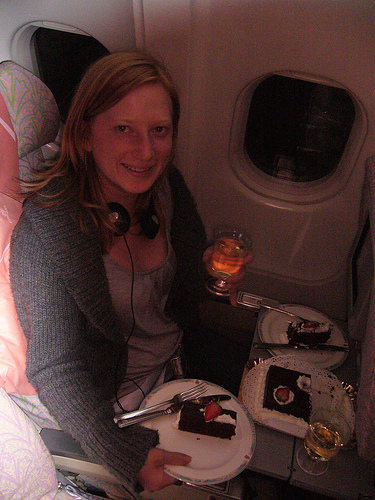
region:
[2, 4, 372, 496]
woman in what appears to be an airplane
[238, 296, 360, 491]
a small grey table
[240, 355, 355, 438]
large section of a cake on a lace-like tray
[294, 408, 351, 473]
a wine glass with yellow liquid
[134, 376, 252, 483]
woman holding a plate with a small piece of cake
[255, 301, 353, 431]
plate with small piece of cake beside larger piece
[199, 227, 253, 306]
woman holding a wine glass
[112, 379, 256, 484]
knife and fork beside each other on plate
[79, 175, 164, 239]
headphones around woman's neck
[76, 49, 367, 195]
small rounded window near woman's head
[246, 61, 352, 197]
The airplane window in front of the woman.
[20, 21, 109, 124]
The airplane window behind the woman's head.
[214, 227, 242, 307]
The glass in the woman's hand.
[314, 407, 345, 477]
The glass on the pull down table in front of the woman.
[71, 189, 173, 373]
The gray shirt the woman is wearing.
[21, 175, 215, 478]
The gray sweater the woman is wearing.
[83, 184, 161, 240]
The earphones around the woman's neck.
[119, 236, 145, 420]
The black wire coming from the earphones.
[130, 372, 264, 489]
The plate in the woman's left hand.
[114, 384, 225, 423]
The fork and butter knife on the plate in the woman's left hand.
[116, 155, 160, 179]
A smile in the photo.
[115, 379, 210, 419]
A fork in the photo.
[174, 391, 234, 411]
A knife in the photo.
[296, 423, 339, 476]
A glass in the photo.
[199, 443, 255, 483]
A plate in the photo.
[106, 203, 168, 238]
Headphones in the photo.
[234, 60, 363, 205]
A window in the photo.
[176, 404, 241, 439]
A cake in the photo.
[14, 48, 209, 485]
A woman in the photo.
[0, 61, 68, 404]
A seat in the photo.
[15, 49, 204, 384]
Woman smiling looking into the camera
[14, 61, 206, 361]
Woman sitting next to window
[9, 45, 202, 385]
Woman wearing black headphones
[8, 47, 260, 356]
Woman Holding glass of liquid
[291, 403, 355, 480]
Glass of liquid on tray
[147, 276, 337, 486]
Three pieces of desert on tray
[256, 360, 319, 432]
Black cake with white and red toppings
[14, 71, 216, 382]
Woman wearing dark sweater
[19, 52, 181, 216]
Woman have dark brown hair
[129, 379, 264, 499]
White plate carrying silver fork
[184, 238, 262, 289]
the glass has wine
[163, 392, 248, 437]
the cake is choclate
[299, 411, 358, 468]
the glass has wine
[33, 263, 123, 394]
the sweater is grey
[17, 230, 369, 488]
the person is in the plane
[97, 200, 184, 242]
the headphones are on the neck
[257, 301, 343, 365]
the knife is silver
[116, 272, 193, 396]
the shirt is grey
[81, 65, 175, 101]
the hair is brown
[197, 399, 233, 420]
the topping is strawberry